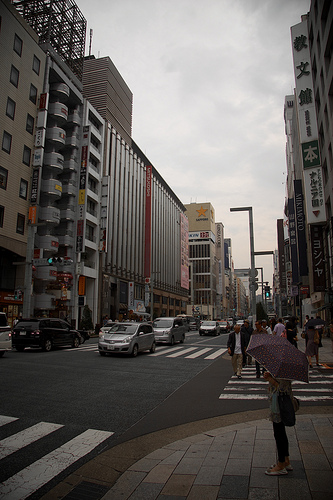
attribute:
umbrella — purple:
[245, 333, 310, 382]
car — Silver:
[97, 320, 155, 356]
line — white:
[216, 391, 332, 400]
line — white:
[223, 381, 329, 391]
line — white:
[226, 377, 326, 384]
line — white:
[205, 345, 230, 358]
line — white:
[0, 419, 66, 456]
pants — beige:
[231, 352, 243, 373]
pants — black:
[271, 421, 290, 460]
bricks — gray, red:
[105, 409, 329, 497]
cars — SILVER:
[100, 317, 185, 349]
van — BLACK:
[20, 316, 79, 344]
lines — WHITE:
[60, 443, 79, 462]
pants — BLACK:
[270, 421, 285, 459]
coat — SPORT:
[242, 329, 245, 348]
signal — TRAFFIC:
[40, 251, 68, 272]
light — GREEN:
[43, 251, 52, 265]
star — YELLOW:
[195, 201, 210, 217]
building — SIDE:
[186, 197, 219, 313]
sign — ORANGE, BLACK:
[76, 278, 82, 298]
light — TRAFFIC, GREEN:
[40, 242, 72, 270]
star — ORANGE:
[195, 197, 208, 221]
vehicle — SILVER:
[97, 320, 152, 352]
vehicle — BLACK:
[19, 313, 86, 354]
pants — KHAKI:
[231, 356, 241, 375]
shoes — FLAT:
[261, 460, 290, 481]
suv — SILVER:
[96, 321, 152, 356]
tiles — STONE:
[154, 457, 230, 491]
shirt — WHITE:
[232, 333, 240, 354]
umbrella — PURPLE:
[252, 324, 310, 383]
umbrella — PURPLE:
[255, 336, 297, 377]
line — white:
[183, 341, 212, 361]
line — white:
[179, 341, 214, 360]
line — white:
[3, 413, 65, 448]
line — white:
[5, 423, 117, 498]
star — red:
[194, 201, 209, 216]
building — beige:
[186, 197, 223, 320]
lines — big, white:
[183, 339, 214, 359]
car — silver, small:
[92, 316, 159, 358]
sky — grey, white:
[13, 1, 313, 294]